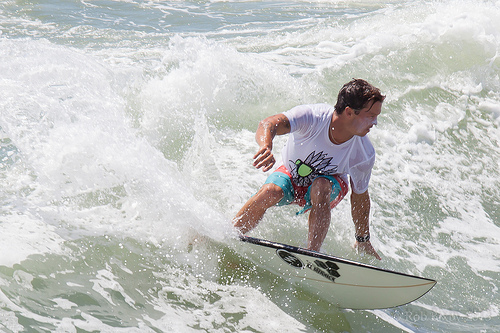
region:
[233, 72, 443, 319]
man surfing in ocean on surfboard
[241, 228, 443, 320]
white surfboard with black designs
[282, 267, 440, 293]
straight line down the center of the surfoard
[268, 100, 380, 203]
white short sleeve t-shirt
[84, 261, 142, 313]
white froth on surface of ocean water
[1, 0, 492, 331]
a scene outside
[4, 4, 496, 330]
a scene during the day time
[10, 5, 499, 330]
an image of a ocean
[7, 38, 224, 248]
a splash of wave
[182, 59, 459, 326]
a surfer riding a wave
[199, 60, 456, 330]
a person on a board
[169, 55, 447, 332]
a surfer that is surfing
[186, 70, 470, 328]
a surfboard under a surfer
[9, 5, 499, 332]
a body of water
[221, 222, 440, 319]
white srufboard with black details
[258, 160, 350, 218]
pair of pink and teal swim trunks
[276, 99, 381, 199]
short sleeve white t-shirt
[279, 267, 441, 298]
straight line down the center of the surfboard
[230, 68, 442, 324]
man surfing on surfboard in ocean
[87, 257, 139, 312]
white froth on top of ocean water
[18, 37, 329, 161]
large ocean wave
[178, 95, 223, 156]
white water splash in ocean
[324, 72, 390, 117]
wet brown hair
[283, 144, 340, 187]
green, grey and black graphic design on white t-shirt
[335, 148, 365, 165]
a white shirt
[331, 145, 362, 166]
the shirt is white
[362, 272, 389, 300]
bottom of the surfboard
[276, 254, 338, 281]
a design on the bottom of the board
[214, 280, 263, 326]
bubbles in the water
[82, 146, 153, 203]
the water is clear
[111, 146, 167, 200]
a splash in the water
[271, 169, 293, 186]
man is wearing shorts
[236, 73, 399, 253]
the man is surfing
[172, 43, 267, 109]
a wave in the water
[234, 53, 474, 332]
a man in the water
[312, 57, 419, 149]
the man has wet hair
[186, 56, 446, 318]
the man is surfing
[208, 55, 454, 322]
the man is on a board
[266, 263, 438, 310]
the bottom of a board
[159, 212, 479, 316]
the board is white and black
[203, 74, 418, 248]
the man is wearing shorts